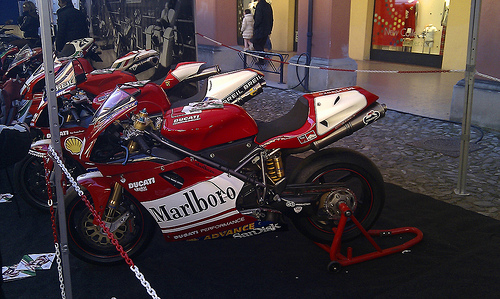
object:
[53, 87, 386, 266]
motorcycle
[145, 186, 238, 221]
marlboro logo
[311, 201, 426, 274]
bike stand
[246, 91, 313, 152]
seat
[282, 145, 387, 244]
wheel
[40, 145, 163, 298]
chain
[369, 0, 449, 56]
window display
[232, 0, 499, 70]
mall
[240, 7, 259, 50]
person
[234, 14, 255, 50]
white clothes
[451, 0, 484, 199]
pole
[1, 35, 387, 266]
motorcycles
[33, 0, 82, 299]
pole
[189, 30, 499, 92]
chain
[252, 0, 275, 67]
person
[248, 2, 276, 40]
black coat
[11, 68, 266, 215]
motorcycle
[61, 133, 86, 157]
shell logo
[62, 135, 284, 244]
adds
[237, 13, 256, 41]
white coat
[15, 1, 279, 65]
people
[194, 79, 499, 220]
path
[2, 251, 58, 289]
booklets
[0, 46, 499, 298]
ground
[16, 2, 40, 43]
person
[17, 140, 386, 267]
wheels